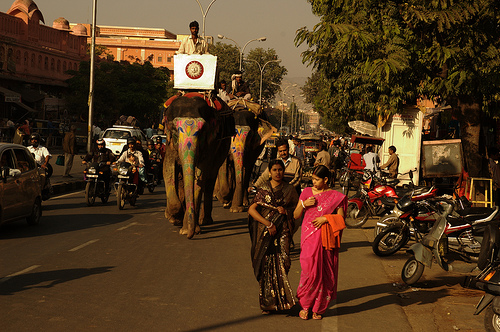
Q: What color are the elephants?
A: Gray.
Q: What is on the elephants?
A: Paint and people.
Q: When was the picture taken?
A: Daytime.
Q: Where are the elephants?
A: In the street.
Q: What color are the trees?
A: Green.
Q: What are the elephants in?
A: The street.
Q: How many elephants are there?
A: Two.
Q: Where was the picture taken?
A: In a city.